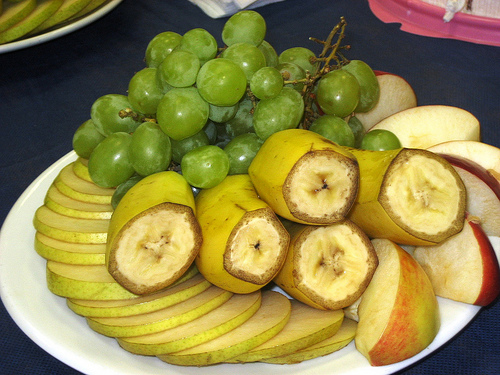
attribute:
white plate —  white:
[1, 147, 498, 374]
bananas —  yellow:
[113, 138, 444, 287]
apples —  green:
[55, 164, 272, 334]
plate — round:
[0, 150, 498, 374]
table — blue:
[1, 2, 498, 374]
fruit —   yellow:
[3, 0, 100, 43]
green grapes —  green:
[70, 7, 412, 185]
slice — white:
[378, 233, 421, 340]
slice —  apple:
[353, 238, 442, 368]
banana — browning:
[357, 117, 472, 250]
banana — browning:
[258, 117, 362, 224]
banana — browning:
[198, 187, 290, 297]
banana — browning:
[83, 149, 220, 300]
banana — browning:
[263, 220, 390, 317]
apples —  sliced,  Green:
[31, 156, 358, 365]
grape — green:
[311, 71, 373, 121]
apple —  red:
[440, 153, 499, 233]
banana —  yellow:
[62, 153, 383, 303]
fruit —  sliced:
[35, 157, 354, 364]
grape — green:
[85, 141, 136, 189]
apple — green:
[58, 168, 105, 208]